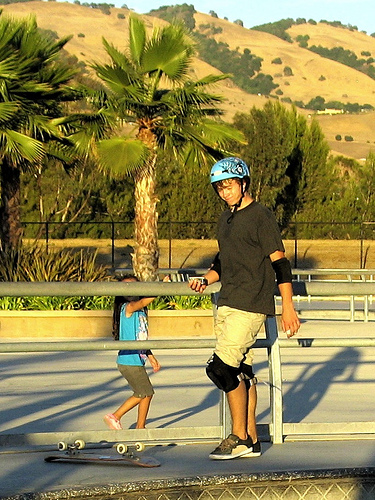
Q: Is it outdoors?
A: Yes, it is outdoors.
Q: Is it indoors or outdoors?
A: It is outdoors.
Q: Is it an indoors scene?
A: No, it is outdoors.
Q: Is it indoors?
A: No, it is outdoors.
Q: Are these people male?
A: No, they are both male and female.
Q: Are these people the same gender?
A: No, they are both male and female.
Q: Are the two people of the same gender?
A: No, they are both male and female.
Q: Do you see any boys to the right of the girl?
A: Yes, there is a boy to the right of the girl.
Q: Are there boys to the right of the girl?
A: Yes, there is a boy to the right of the girl.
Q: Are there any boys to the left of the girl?
A: No, the boy is to the right of the girl.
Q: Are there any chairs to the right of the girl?
A: No, there is a boy to the right of the girl.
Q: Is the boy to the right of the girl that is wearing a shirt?
A: Yes, the boy is to the right of the girl.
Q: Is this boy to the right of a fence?
A: No, the boy is to the right of the girl.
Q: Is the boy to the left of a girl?
A: No, the boy is to the right of a girl.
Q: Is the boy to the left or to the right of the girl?
A: The boy is to the right of the girl.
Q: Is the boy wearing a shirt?
A: Yes, the boy is wearing a shirt.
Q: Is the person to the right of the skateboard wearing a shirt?
A: Yes, the boy is wearing a shirt.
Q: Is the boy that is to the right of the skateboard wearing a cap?
A: No, the boy is wearing a shirt.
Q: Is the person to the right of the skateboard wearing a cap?
A: No, the boy is wearing a shirt.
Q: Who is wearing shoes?
A: The boy is wearing shoes.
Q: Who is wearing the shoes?
A: The boy is wearing shoes.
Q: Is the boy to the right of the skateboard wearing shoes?
A: Yes, the boy is wearing shoes.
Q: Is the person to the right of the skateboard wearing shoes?
A: Yes, the boy is wearing shoes.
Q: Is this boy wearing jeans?
A: No, the boy is wearing shoes.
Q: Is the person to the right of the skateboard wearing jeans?
A: No, the boy is wearing shoes.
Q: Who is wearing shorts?
A: The boy is wearing shorts.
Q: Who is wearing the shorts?
A: The boy is wearing shorts.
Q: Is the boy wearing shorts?
A: Yes, the boy is wearing shorts.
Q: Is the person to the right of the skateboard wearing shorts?
A: Yes, the boy is wearing shorts.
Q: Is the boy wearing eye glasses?
A: No, the boy is wearing shorts.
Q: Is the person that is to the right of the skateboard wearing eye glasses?
A: No, the boy is wearing shorts.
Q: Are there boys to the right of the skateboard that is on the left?
A: Yes, there is a boy to the right of the skateboard.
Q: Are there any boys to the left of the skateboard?
A: No, the boy is to the right of the skateboard.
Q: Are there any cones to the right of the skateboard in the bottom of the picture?
A: No, there is a boy to the right of the skateboard.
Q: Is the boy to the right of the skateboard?
A: Yes, the boy is to the right of the skateboard.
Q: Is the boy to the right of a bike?
A: No, the boy is to the right of the skateboard.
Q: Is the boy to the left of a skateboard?
A: No, the boy is to the right of a skateboard.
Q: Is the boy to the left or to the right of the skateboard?
A: The boy is to the right of the skateboard.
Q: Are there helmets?
A: Yes, there is a helmet.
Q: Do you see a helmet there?
A: Yes, there is a helmet.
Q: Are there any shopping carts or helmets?
A: Yes, there is a helmet.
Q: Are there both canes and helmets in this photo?
A: No, there is a helmet but no canes.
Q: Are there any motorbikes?
A: No, there are no motorbikes.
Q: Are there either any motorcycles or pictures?
A: No, there are no motorcycles or pictures.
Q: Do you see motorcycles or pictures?
A: No, there are no motorcycles or pictures.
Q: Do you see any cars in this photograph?
A: No, there are no cars.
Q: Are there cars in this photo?
A: No, there are no cars.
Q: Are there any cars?
A: No, there are no cars.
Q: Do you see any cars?
A: No, there are no cars.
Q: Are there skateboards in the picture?
A: Yes, there is a skateboard.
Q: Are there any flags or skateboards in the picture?
A: Yes, there is a skateboard.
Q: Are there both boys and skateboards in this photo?
A: Yes, there are both a skateboard and a boy.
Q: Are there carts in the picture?
A: No, there are no carts.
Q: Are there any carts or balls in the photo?
A: No, there are no carts or balls.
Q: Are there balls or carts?
A: No, there are no carts or balls.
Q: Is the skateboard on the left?
A: Yes, the skateboard is on the left of the image.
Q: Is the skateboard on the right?
A: No, the skateboard is on the left of the image.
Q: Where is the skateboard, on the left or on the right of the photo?
A: The skateboard is on the left of the image.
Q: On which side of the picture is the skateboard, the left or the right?
A: The skateboard is on the left of the image.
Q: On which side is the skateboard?
A: The skateboard is on the left of the image.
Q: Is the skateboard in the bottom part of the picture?
A: Yes, the skateboard is in the bottom of the image.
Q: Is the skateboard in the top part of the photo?
A: No, the skateboard is in the bottom of the image.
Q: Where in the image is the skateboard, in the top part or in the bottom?
A: The skateboard is in the bottom of the image.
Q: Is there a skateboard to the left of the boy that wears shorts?
A: Yes, there is a skateboard to the left of the boy.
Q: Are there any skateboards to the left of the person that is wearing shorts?
A: Yes, there is a skateboard to the left of the boy.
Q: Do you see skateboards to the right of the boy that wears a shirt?
A: No, the skateboard is to the left of the boy.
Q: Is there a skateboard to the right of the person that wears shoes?
A: No, the skateboard is to the left of the boy.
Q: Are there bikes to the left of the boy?
A: No, there is a skateboard to the left of the boy.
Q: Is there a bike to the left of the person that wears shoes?
A: No, there is a skateboard to the left of the boy.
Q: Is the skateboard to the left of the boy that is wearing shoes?
A: Yes, the skateboard is to the left of the boy.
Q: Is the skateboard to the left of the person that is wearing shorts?
A: Yes, the skateboard is to the left of the boy.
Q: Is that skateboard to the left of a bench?
A: No, the skateboard is to the left of the boy.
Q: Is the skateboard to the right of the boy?
A: No, the skateboard is to the left of the boy.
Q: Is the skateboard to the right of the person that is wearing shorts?
A: No, the skateboard is to the left of the boy.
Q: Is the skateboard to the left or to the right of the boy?
A: The skateboard is to the left of the boy.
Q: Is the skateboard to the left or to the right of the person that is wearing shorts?
A: The skateboard is to the left of the boy.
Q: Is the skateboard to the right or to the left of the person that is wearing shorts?
A: The skateboard is to the left of the boy.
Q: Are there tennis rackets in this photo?
A: No, there are no tennis rackets.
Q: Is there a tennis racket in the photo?
A: No, there are no rackets.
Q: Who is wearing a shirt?
A: The girl is wearing a shirt.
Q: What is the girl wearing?
A: The girl is wearing a shirt.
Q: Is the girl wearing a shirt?
A: Yes, the girl is wearing a shirt.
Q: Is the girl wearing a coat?
A: No, the girl is wearing a shirt.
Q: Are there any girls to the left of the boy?
A: Yes, there is a girl to the left of the boy.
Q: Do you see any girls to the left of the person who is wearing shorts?
A: Yes, there is a girl to the left of the boy.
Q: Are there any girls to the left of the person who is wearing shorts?
A: Yes, there is a girl to the left of the boy.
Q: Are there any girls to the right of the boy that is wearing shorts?
A: No, the girl is to the left of the boy.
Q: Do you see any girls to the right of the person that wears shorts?
A: No, the girl is to the left of the boy.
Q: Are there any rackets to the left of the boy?
A: No, there is a girl to the left of the boy.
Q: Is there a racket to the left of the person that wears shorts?
A: No, there is a girl to the left of the boy.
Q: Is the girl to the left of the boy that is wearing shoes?
A: Yes, the girl is to the left of the boy.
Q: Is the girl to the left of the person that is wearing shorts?
A: Yes, the girl is to the left of the boy.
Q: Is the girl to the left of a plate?
A: No, the girl is to the left of the boy.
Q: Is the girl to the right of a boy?
A: No, the girl is to the left of a boy.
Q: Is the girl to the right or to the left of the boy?
A: The girl is to the left of the boy.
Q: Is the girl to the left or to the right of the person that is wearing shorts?
A: The girl is to the left of the boy.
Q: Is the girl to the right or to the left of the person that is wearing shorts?
A: The girl is to the left of the boy.